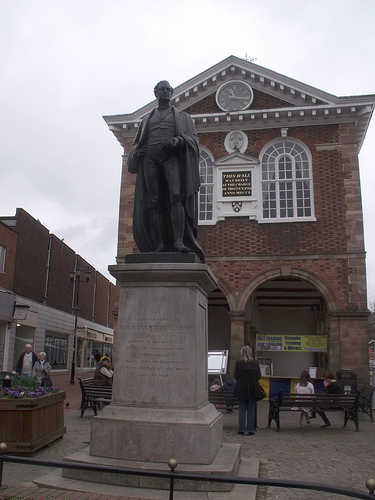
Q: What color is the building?
A: Red and white.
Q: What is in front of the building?
A: A statue.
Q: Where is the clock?
A: On the building.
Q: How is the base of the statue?
A: Engraved.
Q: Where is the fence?
A: In front of the statue.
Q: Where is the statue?
A: In front of building.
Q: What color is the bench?
A: Black.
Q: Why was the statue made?
A: As a memorial.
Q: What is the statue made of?
A: Stone.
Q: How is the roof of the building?
A: Pointed.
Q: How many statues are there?
A: 1.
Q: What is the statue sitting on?
A: Pedestal.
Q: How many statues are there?
A: One.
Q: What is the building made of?
A: Bricks.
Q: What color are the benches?
A: Black and brown.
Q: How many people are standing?
A: Three.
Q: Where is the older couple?
A: Walking on the left.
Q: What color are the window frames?
A: White.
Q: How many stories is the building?
A: Two.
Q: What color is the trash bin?
A: Black.